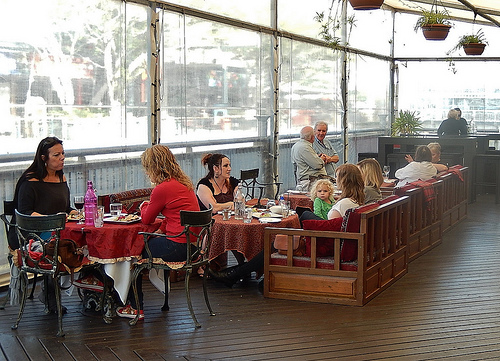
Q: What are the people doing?
A: Eating.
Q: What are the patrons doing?
A: Talking.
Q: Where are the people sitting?
A: Restaurant.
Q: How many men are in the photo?
A: 2.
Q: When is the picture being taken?
A: Daytime.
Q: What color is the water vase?
A: Purple.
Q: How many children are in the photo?
A: 1.